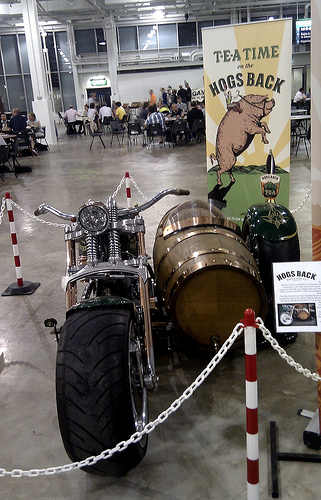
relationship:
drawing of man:
[209, 53, 314, 168] [218, 86, 248, 130]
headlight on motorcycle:
[59, 206, 102, 223] [43, 194, 196, 467]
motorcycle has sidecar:
[43, 194, 196, 467] [145, 209, 293, 290]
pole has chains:
[231, 308, 296, 499] [28, 416, 165, 493]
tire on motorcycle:
[55, 309, 150, 478] [43, 194, 196, 467]